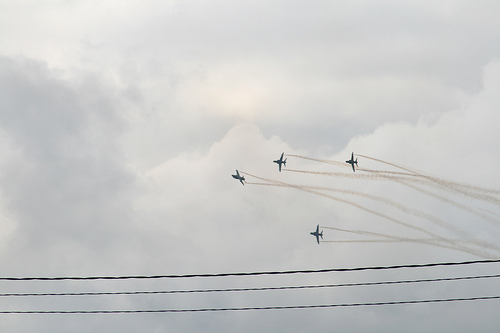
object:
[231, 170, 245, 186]
plane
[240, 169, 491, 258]
smoke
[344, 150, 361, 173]
plane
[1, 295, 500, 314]
electrical wires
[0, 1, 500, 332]
sky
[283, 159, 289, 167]
tail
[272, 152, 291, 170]
airplane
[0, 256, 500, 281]
wires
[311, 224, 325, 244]
fighter